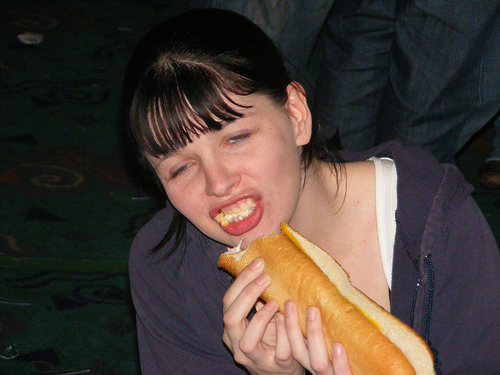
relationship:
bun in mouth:
[214, 211, 232, 225] [203, 190, 269, 240]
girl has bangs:
[126, 20, 500, 375] [122, 62, 229, 154]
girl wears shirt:
[94, 43, 486, 369] [367, 155, 403, 287]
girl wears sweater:
[94, 43, 486, 369] [126, 140, 500, 375]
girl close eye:
[126, 20, 500, 375] [165, 158, 194, 179]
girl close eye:
[126, 20, 500, 375] [215, 125, 252, 150]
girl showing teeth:
[126, 20, 500, 375] [213, 196, 260, 226]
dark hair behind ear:
[115, 9, 297, 158] [278, 82, 313, 149]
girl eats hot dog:
[126, 20, 500, 375] [182, 200, 440, 362]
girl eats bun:
[94, 43, 486, 369] [215, 221, 435, 375]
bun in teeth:
[214, 199, 257, 226] [208, 206, 244, 224]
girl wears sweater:
[94, 43, 486, 369] [124, 131, 495, 373]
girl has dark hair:
[126, 20, 500, 375] [115, 9, 297, 158]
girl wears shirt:
[126, 20, 500, 375] [366, 138, 403, 260]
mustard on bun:
[342, 295, 384, 333] [215, 221, 435, 375]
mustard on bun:
[279, 222, 304, 252] [215, 221, 435, 375]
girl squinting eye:
[126, 20, 500, 375] [169, 152, 195, 182]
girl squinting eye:
[126, 20, 500, 375] [222, 125, 256, 147]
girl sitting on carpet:
[126, 20, 500, 375] [0, 2, 140, 369]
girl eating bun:
[126, 20, 500, 375] [215, 221, 435, 375]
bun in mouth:
[214, 211, 232, 225] [210, 190, 264, 236]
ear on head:
[283, 81, 311, 146] [130, 8, 312, 249]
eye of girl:
[166, 156, 193, 178] [126, 20, 500, 375]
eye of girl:
[218, 127, 255, 148] [126, 20, 500, 375]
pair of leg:
[323, 6, 470, 161] [308, 1, 410, 168]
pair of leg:
[323, 6, 470, 161] [384, 2, 496, 176]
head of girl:
[119, 3, 326, 243] [126, 20, 500, 375]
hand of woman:
[279, 298, 354, 373] [118, 24, 441, 371]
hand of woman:
[209, 257, 291, 367] [118, 24, 441, 371]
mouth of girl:
[203, 190, 269, 240] [126, 20, 500, 375]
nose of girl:
[197, 157, 235, 191] [126, 20, 500, 375]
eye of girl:
[221, 125, 256, 152] [126, 20, 500, 375]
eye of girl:
[164, 150, 197, 184] [126, 20, 500, 375]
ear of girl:
[283, 81, 311, 146] [126, 20, 500, 375]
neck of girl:
[176, 160, 336, 246] [126, 20, 500, 375]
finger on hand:
[305, 306, 330, 372] [287, 310, 349, 372]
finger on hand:
[332, 342, 347, 374] [287, 310, 349, 372]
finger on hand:
[284, 301, 304, 360] [287, 310, 349, 372]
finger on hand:
[275, 314, 286, 359] [223, 266, 294, 372]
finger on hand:
[224, 287, 262, 324] [223, 266, 294, 372]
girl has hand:
[126, 20, 500, 375] [287, 310, 349, 372]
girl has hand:
[126, 20, 500, 375] [223, 266, 294, 372]